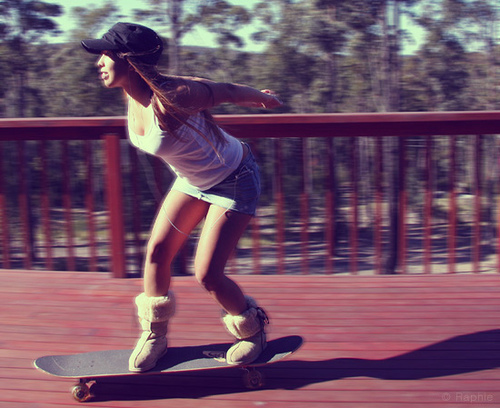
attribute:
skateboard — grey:
[38, 332, 300, 387]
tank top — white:
[119, 100, 251, 194]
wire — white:
[148, 212, 210, 242]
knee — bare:
[198, 263, 222, 295]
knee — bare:
[145, 237, 172, 264]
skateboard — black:
[30, 334, 303, 401]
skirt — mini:
[163, 140, 271, 218]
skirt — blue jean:
[171, 138, 261, 210]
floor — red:
[2, 237, 497, 406]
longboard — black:
[36, 323, 318, 385]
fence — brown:
[0, 107, 499, 274]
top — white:
[129, 76, 226, 183]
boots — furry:
[127, 289, 268, 378]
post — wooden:
[323, 98, 410, 167]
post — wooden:
[304, 121, 392, 253]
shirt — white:
[119, 91, 249, 197]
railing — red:
[2, 113, 495, 279]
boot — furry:
[132, 289, 181, 372]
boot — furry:
[212, 303, 270, 371]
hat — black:
[77, 19, 170, 69]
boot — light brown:
[125, 294, 176, 378]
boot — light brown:
[219, 306, 271, 368]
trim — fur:
[134, 294, 175, 324]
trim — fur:
[215, 300, 270, 337]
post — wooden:
[343, 142, 363, 279]